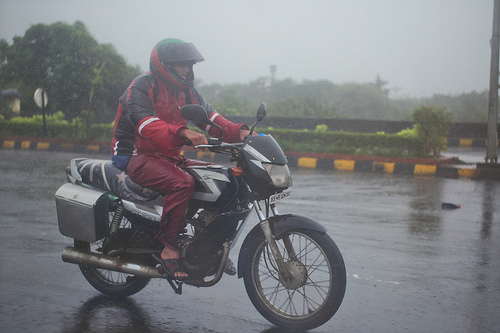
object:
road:
[1, 178, 499, 331]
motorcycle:
[53, 102, 345, 330]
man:
[109, 38, 259, 283]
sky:
[223, 1, 471, 65]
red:
[150, 125, 170, 141]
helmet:
[148, 37, 205, 89]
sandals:
[220, 253, 239, 276]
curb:
[1, 129, 500, 178]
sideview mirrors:
[249, 101, 274, 120]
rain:
[354, 174, 484, 224]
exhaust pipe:
[61, 242, 173, 282]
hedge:
[0, 110, 435, 159]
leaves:
[315, 123, 328, 133]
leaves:
[9, 33, 24, 45]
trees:
[59, 22, 129, 119]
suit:
[111, 70, 247, 248]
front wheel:
[238, 214, 350, 330]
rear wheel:
[72, 209, 160, 299]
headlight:
[265, 162, 295, 187]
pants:
[113, 152, 230, 249]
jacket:
[112, 71, 255, 162]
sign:
[31, 86, 51, 111]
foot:
[160, 243, 187, 279]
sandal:
[150, 247, 194, 282]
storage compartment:
[54, 184, 112, 243]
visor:
[163, 45, 207, 65]